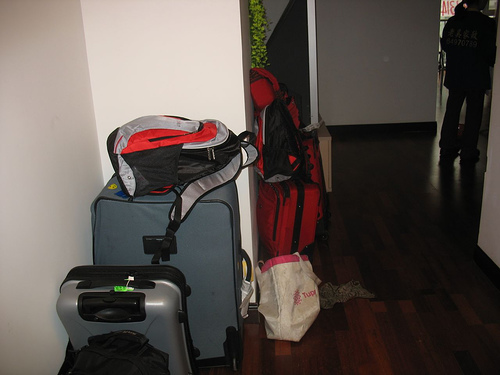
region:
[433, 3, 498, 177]
A person at the doorway moving luggage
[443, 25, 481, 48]
Printed numbers on the back of the jacket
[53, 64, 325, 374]
Packed suitcases and bags on the floor with different colors.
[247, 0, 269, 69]
Green decoration hanging on the white wall.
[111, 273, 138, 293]
Green identification tag on a grey-black suitcase.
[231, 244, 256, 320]
A white tag on the handle of a suitcase.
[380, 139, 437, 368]
Wooden floor in the house.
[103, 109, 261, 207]
A back pack with a mix of black, red and grey colors.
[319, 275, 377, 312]
A piece of cloth lying on the floor.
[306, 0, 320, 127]
A bright, grey upright metallic strip.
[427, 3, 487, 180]
Person standing in the shadow.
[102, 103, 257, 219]
A red, black and grey backpack on a grey suitcase.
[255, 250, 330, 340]
A beige and red canvas bag on floor.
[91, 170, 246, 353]
Large grey cloth suitcase with white tag.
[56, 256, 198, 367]
Silver and black suitcase with green tag.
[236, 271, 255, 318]
White tag on grey suitcase handle.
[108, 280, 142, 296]
Light green tag on suitcase.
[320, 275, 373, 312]
Brown and black cloth on floor.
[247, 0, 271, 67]
Part of leafy green plant.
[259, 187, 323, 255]
Red and black suitcase directly on floor.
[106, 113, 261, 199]
red, black and silver backpack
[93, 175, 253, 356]
large piece of blue luggage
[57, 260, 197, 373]
black and silver hard-side luggage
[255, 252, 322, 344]
pink and white shopping bag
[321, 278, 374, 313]
brown scarf on floor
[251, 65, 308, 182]
red and black backpack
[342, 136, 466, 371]
dark brown hardwood floor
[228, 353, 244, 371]
wheels on luggage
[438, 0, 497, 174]
person standing in doorway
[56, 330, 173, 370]
black bag beside luggage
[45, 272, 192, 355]
gray and black suitcase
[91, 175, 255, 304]
gray and black large luggage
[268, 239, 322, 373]
tan and pink bag for shoping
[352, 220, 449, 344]
dark cherry wood floors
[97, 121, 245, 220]
red, gray, and black backpack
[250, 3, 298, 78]
green outfit peeking out of door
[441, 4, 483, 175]
a person in the shadows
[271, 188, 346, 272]
red and black small luggage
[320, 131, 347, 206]
the corner of a box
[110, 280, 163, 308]
lime green tag on luggage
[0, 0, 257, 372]
The wall is white.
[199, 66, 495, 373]
The floor is made of wood.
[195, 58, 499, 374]
The floor is brown.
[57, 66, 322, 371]
A lot of luggage.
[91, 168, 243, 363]
The luggage is gray.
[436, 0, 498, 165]
A person is in the background.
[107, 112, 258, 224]
A backpack.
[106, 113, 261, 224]
The backpack is gray, red and black.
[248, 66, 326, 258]
The luggage is red.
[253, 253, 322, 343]
A bag.